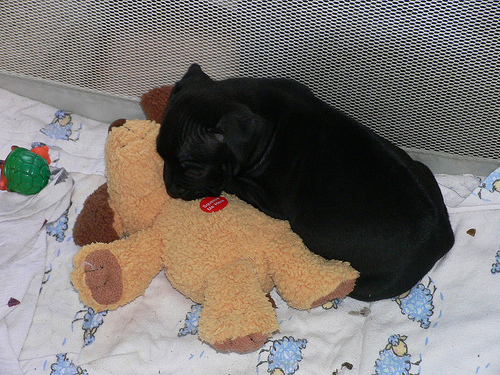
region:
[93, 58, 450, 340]
ppuppy sleeping on stuffed animal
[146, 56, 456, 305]
black puppy curled up on stuffed animal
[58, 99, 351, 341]
brown stuffed puppy dog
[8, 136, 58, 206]
little green turtle ball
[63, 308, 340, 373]
blanket with blue sheep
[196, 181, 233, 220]
"squeeze me here" tag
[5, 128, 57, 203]
rubber play toy for puppy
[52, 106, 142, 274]
big brown ears on stuffed dog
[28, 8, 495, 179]
grid wire of puppy cage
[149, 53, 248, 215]
black puppy with wrinkly face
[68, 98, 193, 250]
the head of a teddy bear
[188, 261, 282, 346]
the leg of a teddy bear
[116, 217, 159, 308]
the arm of a teddy bear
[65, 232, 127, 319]
the paw of a teddy bear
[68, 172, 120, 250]
the ear of a teddy bear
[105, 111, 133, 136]
the nose of a teddy bear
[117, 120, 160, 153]
the mouth of a teddy bear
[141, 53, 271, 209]
the head of a puppy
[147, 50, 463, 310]
a black puppy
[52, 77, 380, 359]
a fuzzy brown teddy bear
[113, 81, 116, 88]
edge of a net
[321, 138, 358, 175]
back of a dog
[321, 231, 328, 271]
body of a dog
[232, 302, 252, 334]
legs of a doll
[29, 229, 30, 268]
part of a sheet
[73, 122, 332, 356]
a cute doll on floor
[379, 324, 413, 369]
a small design on bed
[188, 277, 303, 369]
leg of the doll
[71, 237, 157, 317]
hand of the doll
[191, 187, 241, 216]
a small red symbol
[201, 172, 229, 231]
a small red cloth in doll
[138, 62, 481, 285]
a beautiful black dog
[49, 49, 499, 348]
a dog sleeping on doll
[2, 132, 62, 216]
a green object on bed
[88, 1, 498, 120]
a iron stand on back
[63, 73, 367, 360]
a brown teddy bear